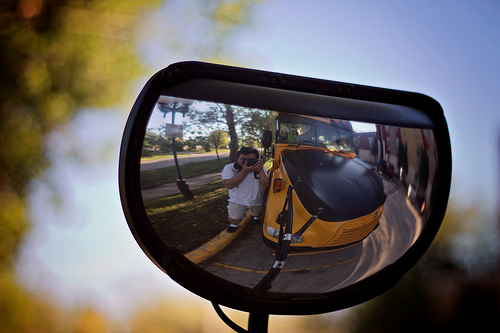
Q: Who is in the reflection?
A: A man.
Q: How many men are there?
A: One.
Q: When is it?
A: Daytime.